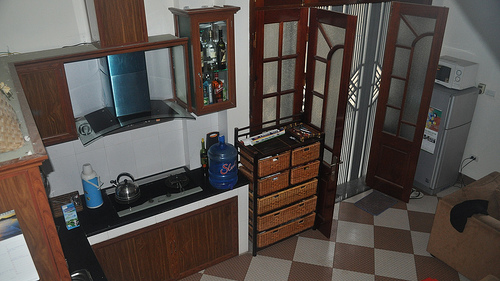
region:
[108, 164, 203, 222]
black cooktop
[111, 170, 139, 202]
silver tea kettle on the cooktop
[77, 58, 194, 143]
silver range hood and vent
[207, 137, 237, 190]
five gallon blue plastic water jug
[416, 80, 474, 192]
small silver refrigerator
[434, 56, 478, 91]
white microwave on top of refrigerator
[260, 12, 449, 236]
french doors in the kitchen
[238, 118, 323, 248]
black rack with brown wicker baskets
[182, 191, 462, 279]
brown and white checkerboard tile floor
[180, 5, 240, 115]
liquor bottles in cabinet to right of range hood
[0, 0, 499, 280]
the interior of a kitchen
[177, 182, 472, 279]
the kitchen's tiled floor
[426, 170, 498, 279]
a small sofa chair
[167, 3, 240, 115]
a liquor cabinet on the wall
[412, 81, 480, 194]
a small fridge in the corner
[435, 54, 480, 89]
a white microwave oven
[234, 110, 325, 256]
a rack of wicker baskets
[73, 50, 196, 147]
a steam hood over the stove top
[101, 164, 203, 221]
a small cooking range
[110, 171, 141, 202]
a kettle on the range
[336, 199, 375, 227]
brown diamond shape on floor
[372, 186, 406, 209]
brown diamond shape on floor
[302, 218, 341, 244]
brown diamond shape on floor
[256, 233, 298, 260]
brown diamond shape on floor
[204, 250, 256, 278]
brown diamond shape on floor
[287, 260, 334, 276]
brown diamond shape on floor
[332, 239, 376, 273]
brown diamond shape on floor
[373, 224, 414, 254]
brown diamond shape on floor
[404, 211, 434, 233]
brown diamond shape on floor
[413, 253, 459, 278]
brown diamond shape on floor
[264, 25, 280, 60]
small frosted glass window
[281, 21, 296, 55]
small frosted glass window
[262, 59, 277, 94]
small frosted glass window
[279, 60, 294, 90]
small frosted glass window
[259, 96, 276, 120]
small frosted glass window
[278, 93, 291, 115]
small frosted glass window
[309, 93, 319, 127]
small frosted glass window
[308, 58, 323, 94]
small frosted glass window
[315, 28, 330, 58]
small frosted glass window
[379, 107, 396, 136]
small frosted glass window